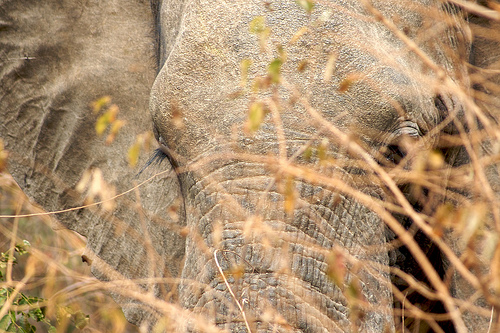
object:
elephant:
[0, 0, 500, 333]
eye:
[382, 128, 421, 159]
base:
[163, 193, 362, 282]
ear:
[0, 0, 187, 329]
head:
[0, 0, 500, 333]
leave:
[0, 314, 35, 333]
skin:
[191, 141, 312, 239]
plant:
[0, 284, 56, 333]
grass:
[0, 0, 500, 332]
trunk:
[165, 150, 392, 333]